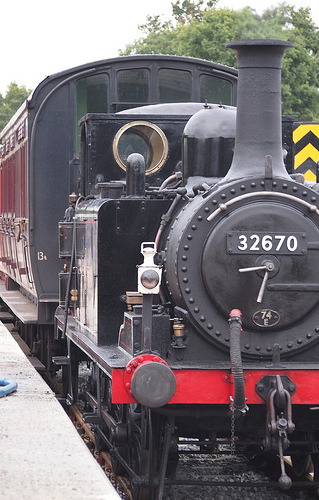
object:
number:
[287, 233, 298, 255]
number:
[237, 233, 298, 254]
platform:
[0, 401, 94, 500]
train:
[0, 38, 319, 500]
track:
[49, 356, 316, 500]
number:
[252, 308, 281, 328]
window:
[71, 70, 111, 155]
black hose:
[266, 344, 272, 352]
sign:
[284, 116, 319, 196]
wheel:
[123, 403, 155, 499]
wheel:
[102, 377, 127, 474]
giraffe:
[117, 298, 189, 380]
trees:
[7, 87, 23, 107]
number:
[237, 234, 248, 251]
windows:
[116, 65, 152, 113]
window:
[202, 75, 232, 111]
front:
[112, 37, 318, 403]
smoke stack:
[223, 32, 295, 188]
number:
[250, 232, 260, 251]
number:
[261, 233, 273, 253]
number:
[274, 233, 286, 253]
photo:
[0, 0, 317, 498]